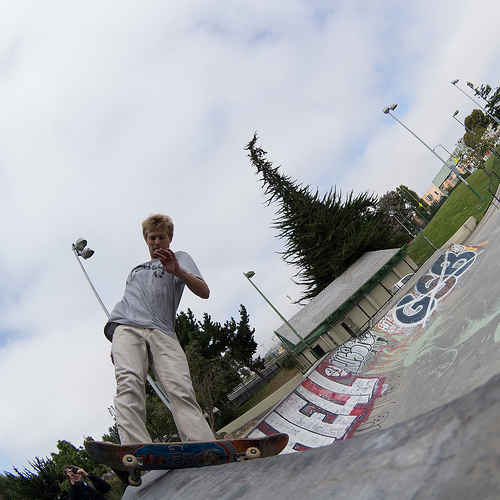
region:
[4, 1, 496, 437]
cloud cover in sky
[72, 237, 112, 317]
two lights on pole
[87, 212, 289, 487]
man standing on skateboard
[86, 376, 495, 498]
skateboard on edge of ramp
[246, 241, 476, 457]
graffiti on skateboard ramp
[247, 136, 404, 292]
branches on pine tree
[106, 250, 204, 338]
short sleeved tee shirt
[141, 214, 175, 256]
blonde hair on head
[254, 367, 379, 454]
white painted block letters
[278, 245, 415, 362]
building with slanted roof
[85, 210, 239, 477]
young man doing trick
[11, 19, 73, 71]
white clouds in blue sky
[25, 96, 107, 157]
white clouds in blue sky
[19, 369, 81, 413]
white clouds in blue sky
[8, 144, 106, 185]
white clouds in blue sky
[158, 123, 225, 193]
white clouds in blue sky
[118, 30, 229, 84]
white clouds in blue sky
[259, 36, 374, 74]
white clouds in blue sky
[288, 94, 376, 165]
white clouds in blue sky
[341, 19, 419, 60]
white clouds in blue sky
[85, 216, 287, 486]
man riding a skateboard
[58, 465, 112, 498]
person taking a picture of skateboarder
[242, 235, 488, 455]
graffitti at skateboard park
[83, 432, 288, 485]
red and blue skateboard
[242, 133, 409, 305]
evergreen tree outside skateboard park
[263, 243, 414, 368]
green and grey building beside skateboard park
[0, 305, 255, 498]
row of trees beyond skateboard park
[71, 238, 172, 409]
metal light post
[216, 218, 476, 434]
concrete wall beside road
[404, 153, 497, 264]
grassy area beside skateboard park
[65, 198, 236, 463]
this is a man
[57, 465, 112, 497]
this is a man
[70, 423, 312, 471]
this is a skate board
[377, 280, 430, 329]
a letter on the ground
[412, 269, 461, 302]
a letter on the ground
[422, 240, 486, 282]
a letter on the ground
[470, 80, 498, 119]
this is a tree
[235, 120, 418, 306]
this is a tree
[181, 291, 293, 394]
this is a tree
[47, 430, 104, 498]
this is a tree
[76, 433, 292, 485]
skateboard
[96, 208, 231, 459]
man on a skateboard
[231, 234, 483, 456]
graffiti on a skate ramp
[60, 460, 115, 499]
person holding up a camera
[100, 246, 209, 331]
skater's grey tee shirt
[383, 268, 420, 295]
roof of a white truck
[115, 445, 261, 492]
three visible yellow skateboard wheels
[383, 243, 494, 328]
crossed out graffiti tag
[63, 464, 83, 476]
camera in a person's hands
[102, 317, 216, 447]
man's khaki colored pants